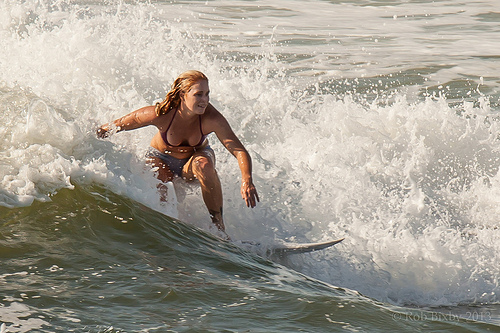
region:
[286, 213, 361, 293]
front part of the machine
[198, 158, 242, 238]
leg of the girl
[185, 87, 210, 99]
eye of the girl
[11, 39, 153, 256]
water raising in to air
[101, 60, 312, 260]
a girl diving in water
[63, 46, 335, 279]
a women skating in water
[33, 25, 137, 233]
a beautiful raise of water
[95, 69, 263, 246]
Girl surfing in ocean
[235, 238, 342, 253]
White surfboard in water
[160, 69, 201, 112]
Strawberry blonde hair on girl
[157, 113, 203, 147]
Bikini top bathing suit on girl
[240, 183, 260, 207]
Girl's left hand stretched forward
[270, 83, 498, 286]
White spray from waves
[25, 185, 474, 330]
Higher side of a wave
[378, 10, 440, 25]
Tiny splash droplets of water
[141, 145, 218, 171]
Gray shorts on girl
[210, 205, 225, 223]
Tattoo on girl's leg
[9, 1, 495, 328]
A pretty woman surfing in the ocean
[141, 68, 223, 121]
she has blonde hair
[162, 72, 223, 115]
She is smiling very broadly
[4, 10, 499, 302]
Surf is foaming up all around her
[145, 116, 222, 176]
She is wearing a bikini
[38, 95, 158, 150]
Her right arm is partially obscured by surf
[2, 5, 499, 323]
the ocean looks pretty rough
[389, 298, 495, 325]
The photographers name and the year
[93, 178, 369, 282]
The surfboard is almost completely obscured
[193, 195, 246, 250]
The lady has a tatoo on her left leg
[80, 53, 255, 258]
surfer in ocean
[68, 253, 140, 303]
white and green ocean waves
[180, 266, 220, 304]
white and green ocean waves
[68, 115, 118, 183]
white and green ocean waves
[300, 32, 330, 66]
white and green ocean waves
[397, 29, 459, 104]
white and green ocean waves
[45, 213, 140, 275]
white and green ocean waves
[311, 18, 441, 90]
white and green ocean waves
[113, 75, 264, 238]
lady in the water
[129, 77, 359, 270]
The woman is surfboarding.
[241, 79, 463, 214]
The water is splashing.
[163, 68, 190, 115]
The lady has wet hair.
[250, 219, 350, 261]
Tip of the surboard in water.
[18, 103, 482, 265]
The waves are splashing.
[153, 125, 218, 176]
The woman is wearing bikini.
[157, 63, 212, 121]
the head of a woman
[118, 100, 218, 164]
the body of a woman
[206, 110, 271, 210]
the left arm of a woman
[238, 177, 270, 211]
the left hand of a woman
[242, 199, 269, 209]
the fingers of a woman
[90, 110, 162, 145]
the right arm of a woman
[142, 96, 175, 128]
the right shoulder of a woman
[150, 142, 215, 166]
the belly of a woman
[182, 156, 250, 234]
the leg of a woman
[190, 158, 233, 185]
the knee of a woman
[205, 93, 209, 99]
person has an eye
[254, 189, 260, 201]
person has a finger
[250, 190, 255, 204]
person has a finger